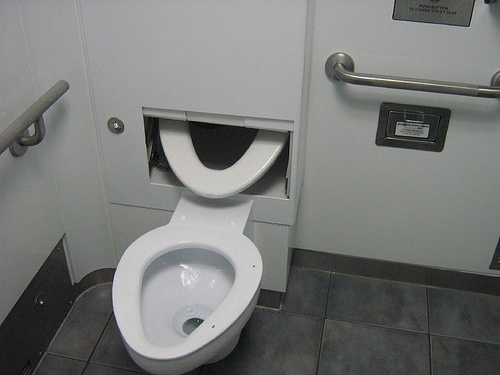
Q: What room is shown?
A: A bathroom.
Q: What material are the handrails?
A: Metal.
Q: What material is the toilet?
A: Porcelain.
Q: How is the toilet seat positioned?
A: Folded up into the wall.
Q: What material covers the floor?
A: Tiles.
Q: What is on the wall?
A: Square opening in wall.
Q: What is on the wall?
A: A handle on a wall.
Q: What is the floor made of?
A: A gray tile floor.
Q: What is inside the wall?
A: A seat to a toilet.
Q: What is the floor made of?
A: A bathroom with a gray tile floor.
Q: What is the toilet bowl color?
A: A white toilet bowl.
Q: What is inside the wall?
A: A toilet seat in the wall.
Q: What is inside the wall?
A: An adjustable toilet seat in the wall.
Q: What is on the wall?
A: A silver metal handlebar.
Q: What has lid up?
A: Toilet.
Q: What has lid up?
A: Toilet.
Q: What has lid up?
A: Toilet.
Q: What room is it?
A: Bathroom.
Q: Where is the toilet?
A: On the ground.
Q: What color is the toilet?
A: White.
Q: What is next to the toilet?
A: A bar.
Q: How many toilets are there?
A: One.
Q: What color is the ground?
A: Silver.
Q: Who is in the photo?
A: No one.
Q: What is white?
A: The toilet.